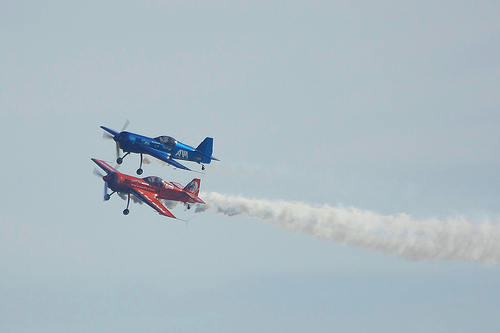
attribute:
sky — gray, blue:
[191, 43, 453, 155]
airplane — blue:
[100, 117, 219, 172]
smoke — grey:
[199, 182, 498, 264]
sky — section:
[354, 282, 439, 321]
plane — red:
[90, 155, 205, 218]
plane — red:
[92, 156, 244, 242]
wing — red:
[133, 187, 183, 220]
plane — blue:
[96, 119, 221, 175]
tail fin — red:
[184, 174, 202, 199]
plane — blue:
[105, 124, 255, 208]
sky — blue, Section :
[0, 0, 499, 331]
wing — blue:
[155, 151, 192, 171]